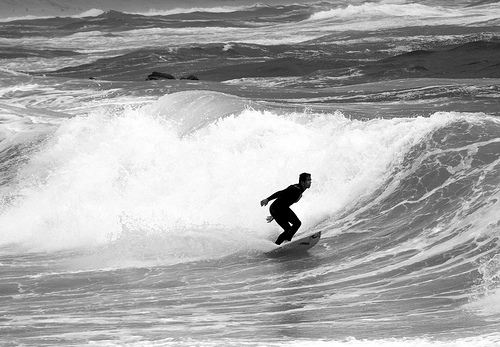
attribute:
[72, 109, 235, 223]
water — stirred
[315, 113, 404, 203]
water — stirred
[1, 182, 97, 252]
water — stirred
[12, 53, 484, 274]
waves — crashing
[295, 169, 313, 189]
hair — black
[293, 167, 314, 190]
hair — short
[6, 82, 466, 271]
wave — crashing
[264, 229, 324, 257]
surfboard — white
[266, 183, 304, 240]
wetsuit — black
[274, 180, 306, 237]
wetsuit — black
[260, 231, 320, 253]
surfboard — long, white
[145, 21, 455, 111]
ripples — small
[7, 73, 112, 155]
ripples — small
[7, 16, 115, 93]
ripples — small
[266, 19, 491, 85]
ripples — small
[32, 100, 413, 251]
spray — white